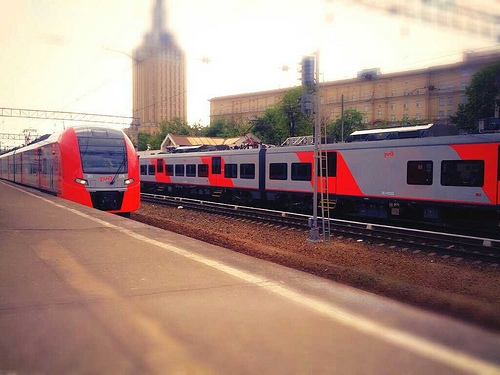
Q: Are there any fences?
A: No, there are no fences.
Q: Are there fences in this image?
A: No, there are no fences.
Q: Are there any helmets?
A: No, there are no helmets.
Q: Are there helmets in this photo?
A: No, there are no helmets.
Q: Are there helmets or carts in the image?
A: No, there are no helmets or carts.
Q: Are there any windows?
A: Yes, there is a window.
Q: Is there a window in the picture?
A: Yes, there is a window.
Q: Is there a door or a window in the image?
A: Yes, there is a window.